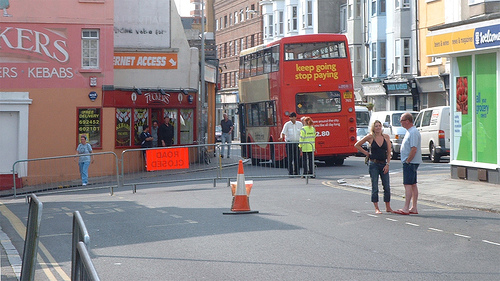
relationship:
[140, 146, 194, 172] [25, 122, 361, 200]
sign on barricade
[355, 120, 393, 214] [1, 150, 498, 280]
people standing on street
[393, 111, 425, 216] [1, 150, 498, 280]
man standing on street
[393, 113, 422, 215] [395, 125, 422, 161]
man in white shirt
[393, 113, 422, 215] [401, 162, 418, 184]
man in blue shorts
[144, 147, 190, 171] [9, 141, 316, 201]
sign on barricade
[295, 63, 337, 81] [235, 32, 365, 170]
sign on bus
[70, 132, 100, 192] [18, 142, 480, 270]
person walking down street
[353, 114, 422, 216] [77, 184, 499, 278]
people standing on street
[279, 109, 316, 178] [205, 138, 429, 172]
people standing on street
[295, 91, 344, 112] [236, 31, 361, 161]
window on bus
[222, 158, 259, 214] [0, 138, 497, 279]
traffic cone in road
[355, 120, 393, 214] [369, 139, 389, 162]
people wearing shirt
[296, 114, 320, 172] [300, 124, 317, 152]
woman wearing safety shirt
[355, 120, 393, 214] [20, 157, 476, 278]
people talking in street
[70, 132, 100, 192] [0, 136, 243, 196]
person walking on sidewalk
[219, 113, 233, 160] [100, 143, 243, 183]
man walking on sidewalk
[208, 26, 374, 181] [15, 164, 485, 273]
bus driving down road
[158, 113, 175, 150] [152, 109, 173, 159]
man standing at door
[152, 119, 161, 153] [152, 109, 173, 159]
man standing at door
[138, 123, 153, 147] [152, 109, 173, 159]
man standing at door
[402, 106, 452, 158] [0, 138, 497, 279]
car parked on road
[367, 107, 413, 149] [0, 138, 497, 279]
car parked on road